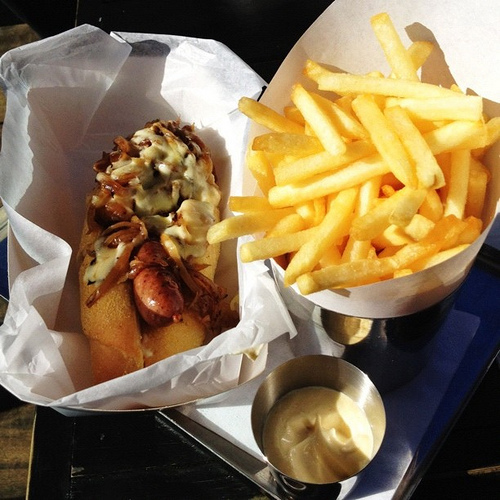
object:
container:
[249, 352, 388, 500]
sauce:
[263, 386, 372, 459]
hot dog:
[133, 267, 186, 326]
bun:
[77, 205, 144, 385]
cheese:
[107, 121, 222, 276]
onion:
[85, 240, 137, 307]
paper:
[0, 22, 300, 409]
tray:
[154, 213, 500, 499]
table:
[2, 294, 39, 498]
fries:
[206, 11, 500, 298]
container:
[240, 0, 500, 317]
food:
[76, 13, 493, 485]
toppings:
[77, 118, 223, 322]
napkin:
[174, 333, 295, 462]